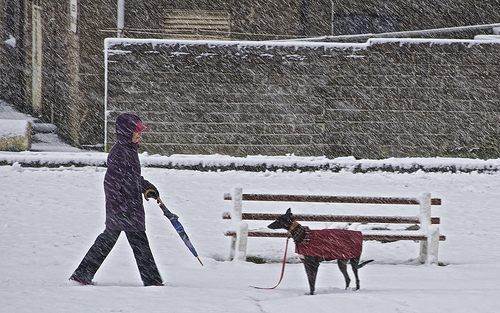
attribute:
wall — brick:
[105, 39, 498, 158]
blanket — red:
[268, 209, 372, 298]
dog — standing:
[248, 202, 401, 301]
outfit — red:
[286, 221, 366, 265]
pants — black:
[69, 222, 164, 291]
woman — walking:
[69, 112, 169, 286]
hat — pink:
[130, 120, 149, 133]